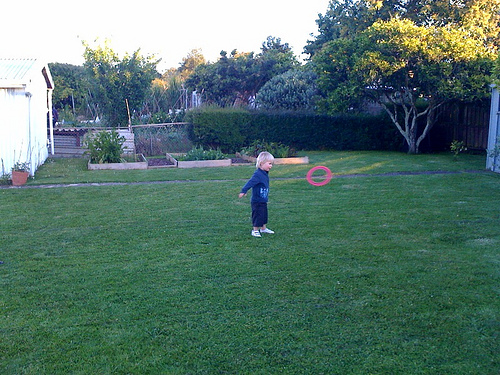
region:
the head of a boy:
[252, 148, 279, 175]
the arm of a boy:
[241, 171, 256, 196]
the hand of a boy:
[234, 185, 245, 203]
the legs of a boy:
[249, 197, 273, 232]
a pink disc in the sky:
[303, 162, 340, 195]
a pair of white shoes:
[246, 224, 276, 242]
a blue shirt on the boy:
[238, 168, 275, 205]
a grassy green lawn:
[0, 148, 497, 373]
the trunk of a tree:
[401, 130, 424, 154]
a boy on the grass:
[234, 147, 283, 251]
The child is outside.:
[119, 118, 398, 298]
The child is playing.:
[172, 136, 372, 268]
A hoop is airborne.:
[292, 154, 338, 196]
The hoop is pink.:
[290, 152, 363, 199]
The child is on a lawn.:
[0, 142, 491, 374]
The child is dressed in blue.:
[227, 165, 281, 236]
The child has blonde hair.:
[247, 145, 282, 172]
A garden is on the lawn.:
[65, 118, 318, 181]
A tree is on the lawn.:
[312, 17, 497, 159]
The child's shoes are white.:
[235, 218, 283, 245]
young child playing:
[255, 151, 273, 241]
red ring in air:
[305, 165, 330, 185]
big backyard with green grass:
[0, 185, 495, 366]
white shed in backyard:
[0, 51, 50, 156]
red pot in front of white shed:
[10, 170, 25, 180]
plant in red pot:
[11, 160, 26, 170]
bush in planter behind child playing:
[85, 130, 120, 160]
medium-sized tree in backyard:
[325, 20, 475, 150]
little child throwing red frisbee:
[245, 145, 330, 235]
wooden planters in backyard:
[86, 155, 236, 167]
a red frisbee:
[303, 162, 331, 187]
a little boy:
[235, 146, 270, 236]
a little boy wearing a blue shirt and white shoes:
[235, 150, 271, 235]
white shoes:
[250, 225, 275, 235]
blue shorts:
[247, 200, 267, 225]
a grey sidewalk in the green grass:
[0, 165, 498, 191]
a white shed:
[0, 55, 51, 176]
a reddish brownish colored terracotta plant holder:
[6, 165, 26, 180]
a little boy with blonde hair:
[235, 150, 275, 236]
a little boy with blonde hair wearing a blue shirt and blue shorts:
[236, 150, 276, 239]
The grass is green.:
[211, 307, 332, 371]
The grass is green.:
[221, 221, 345, 332]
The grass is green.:
[223, 273, 368, 371]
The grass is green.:
[185, 238, 340, 370]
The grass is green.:
[286, 302, 379, 372]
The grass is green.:
[283, 307, 345, 356]